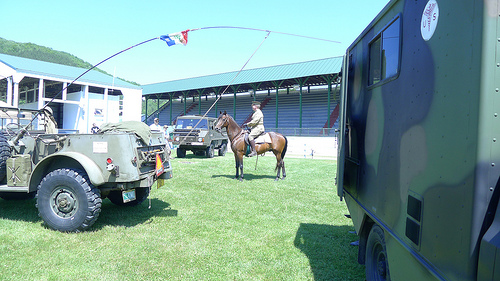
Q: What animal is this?
A: Horse.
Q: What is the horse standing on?
A: Grass.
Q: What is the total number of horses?
A: 1.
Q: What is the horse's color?
A: Brown.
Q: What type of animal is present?
A: Horse.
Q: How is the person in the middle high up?
A: On a horse.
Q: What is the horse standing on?
A: Grass.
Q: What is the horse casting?
A: Shadow.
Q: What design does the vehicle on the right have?
A: Camouflage.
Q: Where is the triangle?
A: On the Jeep.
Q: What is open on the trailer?
A: Door.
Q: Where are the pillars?
A: On the stands.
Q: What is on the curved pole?
A: Flag.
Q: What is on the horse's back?
A: Saddle and person.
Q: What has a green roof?
A: White building.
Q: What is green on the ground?
A: Grass.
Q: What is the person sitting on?
A: A horse.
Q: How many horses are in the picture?
A: One.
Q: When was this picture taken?
A: During the day.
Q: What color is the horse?
A: Brown.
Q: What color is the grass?
A: Green.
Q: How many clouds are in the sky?
A: Zero.